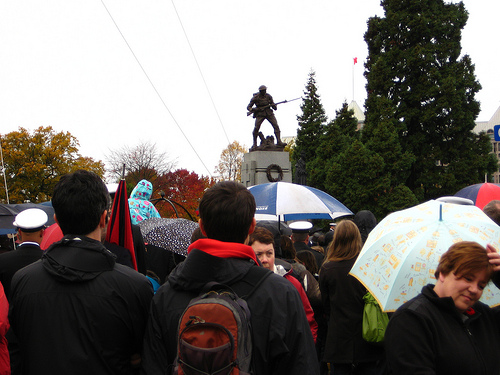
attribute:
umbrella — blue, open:
[240, 181, 356, 227]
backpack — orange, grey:
[172, 260, 276, 374]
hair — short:
[435, 240, 496, 284]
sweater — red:
[279, 266, 320, 348]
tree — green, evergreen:
[291, 65, 328, 191]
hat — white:
[12, 206, 51, 233]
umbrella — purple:
[136, 214, 199, 259]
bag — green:
[360, 287, 392, 346]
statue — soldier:
[245, 83, 305, 151]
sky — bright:
[1, 2, 499, 194]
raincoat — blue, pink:
[128, 177, 162, 227]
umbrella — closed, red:
[104, 157, 140, 275]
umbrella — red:
[448, 171, 500, 209]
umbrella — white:
[349, 197, 498, 319]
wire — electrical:
[95, 1, 212, 175]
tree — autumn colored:
[152, 168, 223, 222]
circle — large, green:
[264, 162, 285, 185]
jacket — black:
[144, 236, 327, 375]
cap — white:
[287, 218, 315, 235]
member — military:
[287, 218, 323, 270]